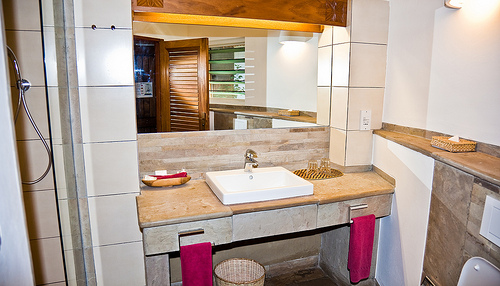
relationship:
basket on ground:
[212, 252, 268, 283] [174, 261, 334, 281]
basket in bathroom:
[212, 256, 268, 285] [4, 4, 495, 280]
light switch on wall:
[360, 108, 374, 135] [4, 0, 393, 286]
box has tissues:
[431, 131, 476, 150] [446, 132, 460, 143]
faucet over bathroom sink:
[242, 147, 261, 173] [209, 165, 311, 194]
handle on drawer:
[178, 224, 206, 238] [144, 217, 238, 256]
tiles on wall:
[318, 0, 392, 170] [4, 0, 393, 286]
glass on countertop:
[307, 157, 324, 173] [136, 163, 394, 226]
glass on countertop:
[318, 162, 331, 174] [136, 163, 394, 226]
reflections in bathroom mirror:
[138, 27, 322, 130] [134, 18, 332, 135]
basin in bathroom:
[201, 159, 317, 209] [0, 1, 499, 284]